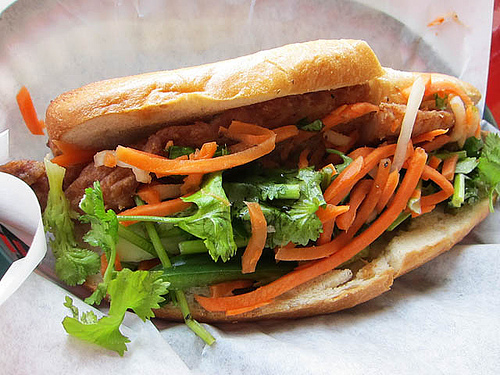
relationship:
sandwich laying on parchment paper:
[46, 41, 495, 320] [0, 0, 488, 369]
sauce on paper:
[425, 8, 463, 34] [336, 1, 491, 94]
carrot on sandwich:
[320, 146, 430, 271] [46, 41, 495, 320]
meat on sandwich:
[65, 162, 136, 210] [46, 41, 495, 320]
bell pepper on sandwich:
[139, 257, 287, 287] [46, 41, 495, 320]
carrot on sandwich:
[192, 145, 426, 311] [66, 41, 473, 308]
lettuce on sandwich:
[183, 201, 250, 262] [66, 41, 473, 308]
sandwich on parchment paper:
[66, 41, 473, 308] [264, 349, 394, 370]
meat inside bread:
[344, 89, 475, 139] [53, 45, 387, 118]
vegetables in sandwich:
[47, 137, 486, 352] [66, 41, 473, 308]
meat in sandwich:
[360, 99, 454, 139] [66, 41, 473, 308]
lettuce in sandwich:
[121, 174, 236, 262] [53, 29, 467, 325]